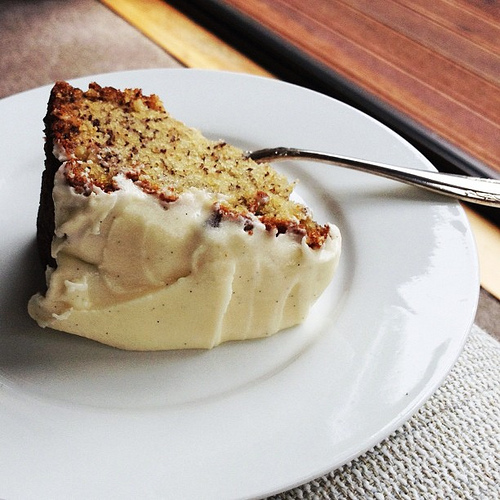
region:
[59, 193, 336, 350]
Frosting on the edge of a sweet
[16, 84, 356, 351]
A sweet food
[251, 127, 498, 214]
An eating utensil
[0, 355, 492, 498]
The edge of a white plate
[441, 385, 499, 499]
A table mat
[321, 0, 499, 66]
A wooden floor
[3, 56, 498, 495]
A light meal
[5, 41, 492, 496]
A light dessert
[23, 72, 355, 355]
A sweet bakery good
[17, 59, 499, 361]
Food sitting on a plate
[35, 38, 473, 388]
slice of cake on a plate.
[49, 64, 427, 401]
delicious slice of cake on a plate.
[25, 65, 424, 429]
slice of cake on a white plate.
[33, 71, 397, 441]
tasty slice of cake on a white plate.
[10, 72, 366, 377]
slice of cake with white frosting on a plate.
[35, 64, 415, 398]
sweet slice of cake with frosting on a plate.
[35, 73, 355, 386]
tempting piece of cake.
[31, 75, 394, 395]
tempting slice of cake on a dish.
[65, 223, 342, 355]
creamy frosting on some cake.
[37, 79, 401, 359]
cake on a dish with eating utensil.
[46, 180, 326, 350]
Icing of the cake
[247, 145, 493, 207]
section of fork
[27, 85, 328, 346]
Piece of cake on a plate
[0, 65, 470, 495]
The cake is resting on a ceramic plate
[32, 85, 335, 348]
The piece of cake is triangular shaped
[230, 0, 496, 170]
Section of wooden board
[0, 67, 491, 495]
The plate with the piece of cake is resting on a rug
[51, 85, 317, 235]
Part of the cake without icing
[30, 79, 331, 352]
The texture of the cake is rough instead of smooth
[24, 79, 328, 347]
The cake is irregularly shaped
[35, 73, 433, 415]
The cake is on a plate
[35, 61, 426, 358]
The plate is white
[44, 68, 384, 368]
The cake has white frosting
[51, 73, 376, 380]
The cake has frosting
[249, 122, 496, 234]
There is silverware on the plate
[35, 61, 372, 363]
The cake is yellow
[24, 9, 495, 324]
The plate is on a table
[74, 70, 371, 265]
A piece of the cake has been eaten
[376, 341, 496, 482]
There is a white table mat underneath the plate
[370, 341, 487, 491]
There is a table mat underneath the plate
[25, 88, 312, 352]
this is a cake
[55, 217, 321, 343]
the cake has cream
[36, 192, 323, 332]
the cream is white in color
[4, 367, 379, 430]
the cake is on a plate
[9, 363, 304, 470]
the plate is white in color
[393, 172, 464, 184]
this is a fork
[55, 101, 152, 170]
the cake is brown in color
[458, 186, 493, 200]
the fork is shiny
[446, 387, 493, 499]
this is a woven table mat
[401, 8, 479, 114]
the table is wooden